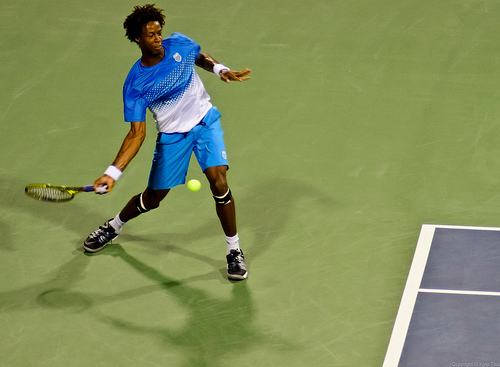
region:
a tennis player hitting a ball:
[17, 1, 260, 300]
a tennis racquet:
[15, 175, 114, 204]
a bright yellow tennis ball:
[185, 178, 200, 194]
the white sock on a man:
[220, 230, 245, 254]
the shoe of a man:
[221, 245, 253, 282]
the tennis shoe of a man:
[78, 220, 123, 253]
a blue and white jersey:
[111, 33, 230, 140]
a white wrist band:
[207, 60, 227, 77]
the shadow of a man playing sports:
[19, 251, 300, 361]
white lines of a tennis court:
[363, 205, 465, 365]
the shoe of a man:
[80, 215, 121, 259]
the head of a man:
[122, 3, 169, 63]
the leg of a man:
[190, 123, 251, 288]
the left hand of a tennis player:
[210, 59, 257, 85]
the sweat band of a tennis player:
[210, 187, 237, 212]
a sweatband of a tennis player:
[131, 188, 158, 220]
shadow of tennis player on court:
[154, 176, 339, 256]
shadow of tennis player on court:
[42, 243, 307, 365]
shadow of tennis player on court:
[0, 247, 86, 310]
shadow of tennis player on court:
[0, 169, 102, 251]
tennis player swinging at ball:
[23, 4, 250, 283]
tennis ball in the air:
[186, 177, 201, 192]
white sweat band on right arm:
[104, 165, 121, 179]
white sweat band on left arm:
[212, 63, 227, 75]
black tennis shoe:
[224, 248, 246, 278]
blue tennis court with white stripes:
[378, 221, 499, 364]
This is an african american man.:
[104, 2, 271, 318]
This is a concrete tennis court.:
[292, 20, 481, 364]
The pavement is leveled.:
[303, 12, 489, 341]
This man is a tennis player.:
[35, 9, 295, 315]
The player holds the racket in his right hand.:
[13, 82, 148, 223]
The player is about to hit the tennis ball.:
[19, 5, 279, 308]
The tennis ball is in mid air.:
[166, 178, 209, 190]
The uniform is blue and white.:
[92, 15, 237, 180]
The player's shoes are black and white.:
[98, 205, 255, 289]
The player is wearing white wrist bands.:
[91, 158, 123, 194]